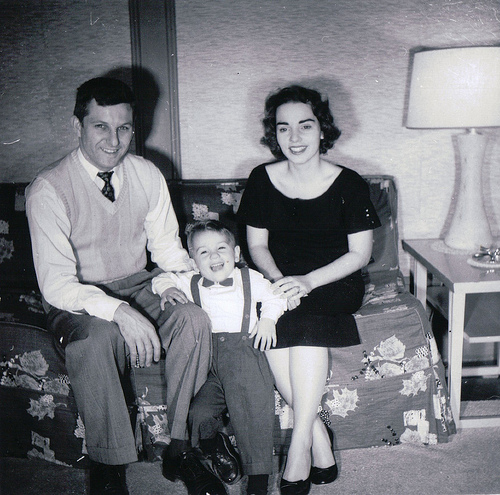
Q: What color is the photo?
A: Black and White.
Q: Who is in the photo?
A: A family.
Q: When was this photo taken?
A: Daytime.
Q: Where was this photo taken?
A: Living Room.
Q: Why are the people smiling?
A: For the camera.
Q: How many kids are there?
A: 1.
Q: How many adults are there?
A: 2.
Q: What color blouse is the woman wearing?
A: Black.